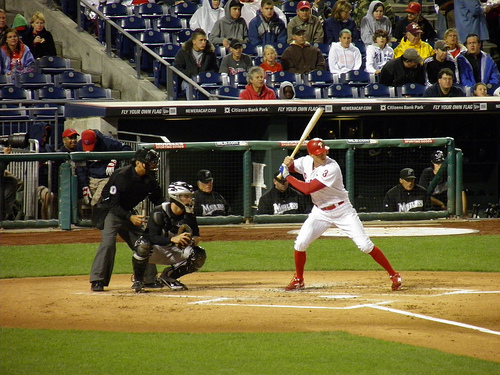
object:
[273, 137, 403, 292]
man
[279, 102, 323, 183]
bat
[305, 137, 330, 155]
helmet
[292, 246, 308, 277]
socks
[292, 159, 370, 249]
uniform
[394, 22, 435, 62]
man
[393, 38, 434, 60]
shirt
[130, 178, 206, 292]
man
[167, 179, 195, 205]
helmet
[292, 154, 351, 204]
shirt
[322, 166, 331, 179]
three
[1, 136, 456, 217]
fence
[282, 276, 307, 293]
shoes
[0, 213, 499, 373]
field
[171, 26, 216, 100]
person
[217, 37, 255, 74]
person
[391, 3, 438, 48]
person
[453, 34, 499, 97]
person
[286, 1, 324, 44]
person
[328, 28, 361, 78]
person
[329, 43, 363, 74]
white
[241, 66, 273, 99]
woman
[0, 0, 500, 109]
seats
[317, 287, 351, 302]
plate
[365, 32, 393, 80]
person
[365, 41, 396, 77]
sweatshirt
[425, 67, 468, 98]
man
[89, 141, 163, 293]
umpire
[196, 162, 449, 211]
team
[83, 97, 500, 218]
dugout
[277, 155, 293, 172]
hand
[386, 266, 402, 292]
sneakers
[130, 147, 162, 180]
helmet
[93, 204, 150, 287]
pants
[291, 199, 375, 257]
pants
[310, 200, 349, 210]
belt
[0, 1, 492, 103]
fans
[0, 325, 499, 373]
grass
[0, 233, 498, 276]
grass